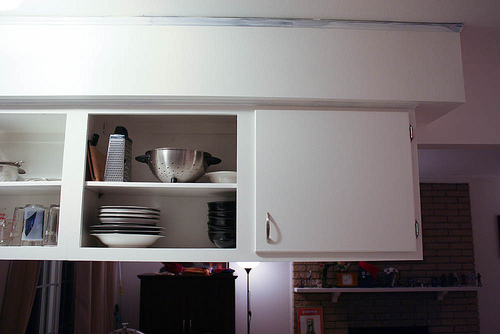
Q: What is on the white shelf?
A: Figurines and clocks.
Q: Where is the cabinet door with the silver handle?
A: The kitchen.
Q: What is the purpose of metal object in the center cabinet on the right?
A: To strain water from pasta.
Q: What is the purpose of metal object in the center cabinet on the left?
A: To shred food.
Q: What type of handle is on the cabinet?
A: A silver handle.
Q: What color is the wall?
A: White.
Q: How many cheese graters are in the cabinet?
A: One.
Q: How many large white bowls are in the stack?
A: Three.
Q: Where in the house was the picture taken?
A: The kitchen.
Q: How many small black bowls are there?
A: Five.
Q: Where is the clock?
A: On the hearth.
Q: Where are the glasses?
A: In the cabinet.